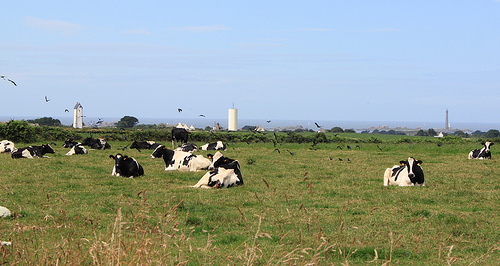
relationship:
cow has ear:
[370, 147, 432, 201] [403, 152, 407, 168]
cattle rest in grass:
[19, 127, 500, 196] [255, 150, 360, 265]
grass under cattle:
[255, 150, 360, 265] [19, 127, 500, 196]